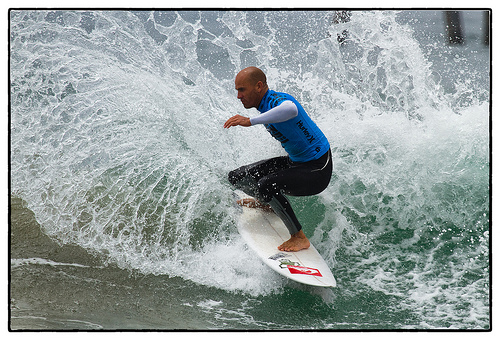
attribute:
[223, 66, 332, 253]
man — surfing, squatting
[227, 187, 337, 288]
surfboard — white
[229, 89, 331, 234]
wetsuit — blue, black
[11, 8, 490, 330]
ocean — green, white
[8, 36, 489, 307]
wave — white, turquoise, green, crashing, large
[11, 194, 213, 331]
water — brown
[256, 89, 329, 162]
shirt — blue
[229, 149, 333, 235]
pants — black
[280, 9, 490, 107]
surf spray — white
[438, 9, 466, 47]
pillar — wooden